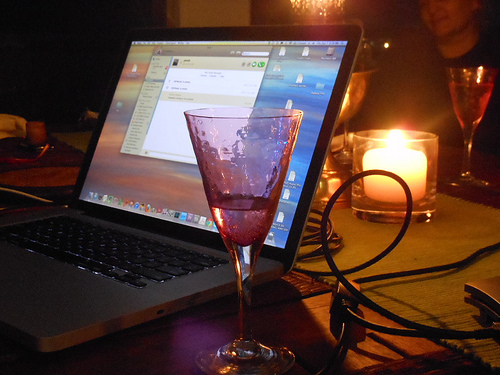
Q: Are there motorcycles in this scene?
A: No, there are no motorcycles.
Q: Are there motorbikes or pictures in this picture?
A: No, there are no motorbikes or pictures.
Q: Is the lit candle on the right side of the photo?
A: Yes, the candle is on the right of the image.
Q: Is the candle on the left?
A: No, the candle is on the right of the image.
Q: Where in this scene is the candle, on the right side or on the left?
A: The candle is on the right of the image.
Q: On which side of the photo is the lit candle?
A: The candle is on the right of the image.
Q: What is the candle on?
A: The candle is on the table.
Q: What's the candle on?
A: The candle is on the table.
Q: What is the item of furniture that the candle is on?
A: The piece of furniture is a table.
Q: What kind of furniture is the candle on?
A: The candle is on the table.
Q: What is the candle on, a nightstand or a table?
A: The candle is on a table.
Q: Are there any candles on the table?
A: Yes, there is a candle on the table.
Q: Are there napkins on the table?
A: No, there is a candle on the table.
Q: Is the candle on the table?
A: Yes, the candle is on the table.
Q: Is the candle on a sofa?
A: No, the candle is on the table.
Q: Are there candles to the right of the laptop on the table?
A: Yes, there is a candle to the right of the laptop.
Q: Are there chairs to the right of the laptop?
A: No, there is a candle to the right of the laptop.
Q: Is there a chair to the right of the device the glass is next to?
A: No, there is a candle to the right of the laptop.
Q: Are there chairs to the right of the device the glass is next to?
A: No, there is a candle to the right of the laptop.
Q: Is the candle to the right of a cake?
A: No, the candle is to the right of a laptop.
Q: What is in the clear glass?
A: The candle is in the glass.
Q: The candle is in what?
A: The candle is in the glass.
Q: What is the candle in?
A: The candle is in the glass.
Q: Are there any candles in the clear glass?
A: Yes, there is a candle in the glass.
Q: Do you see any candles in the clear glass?
A: Yes, there is a candle in the glass.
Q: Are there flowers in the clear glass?
A: No, there is a candle in the glass.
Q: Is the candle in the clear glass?
A: Yes, the candle is in the glass.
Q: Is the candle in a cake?
A: No, the candle is in the glass.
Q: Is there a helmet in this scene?
A: No, there are no helmets.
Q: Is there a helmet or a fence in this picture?
A: No, there are no helmets or fences.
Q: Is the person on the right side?
A: Yes, the person is on the right of the image.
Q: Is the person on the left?
A: No, the person is on the right of the image.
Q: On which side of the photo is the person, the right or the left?
A: The person is on the right of the image.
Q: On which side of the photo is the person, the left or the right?
A: The person is on the right of the image.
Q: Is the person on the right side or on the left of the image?
A: The person is on the right of the image.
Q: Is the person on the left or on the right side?
A: The person is on the right of the image.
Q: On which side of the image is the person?
A: The person is on the right of the image.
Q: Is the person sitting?
A: Yes, the person is sitting.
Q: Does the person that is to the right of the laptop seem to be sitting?
A: Yes, the person is sitting.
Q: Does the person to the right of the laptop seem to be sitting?
A: Yes, the person is sitting.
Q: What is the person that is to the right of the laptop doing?
A: The person is sitting.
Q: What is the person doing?
A: The person is sitting.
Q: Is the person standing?
A: No, the person is sitting.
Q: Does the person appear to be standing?
A: No, the person is sitting.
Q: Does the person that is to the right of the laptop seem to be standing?
A: No, the person is sitting.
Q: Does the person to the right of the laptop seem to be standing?
A: No, the person is sitting.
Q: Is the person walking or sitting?
A: The person is sitting.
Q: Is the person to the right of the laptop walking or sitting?
A: The person is sitting.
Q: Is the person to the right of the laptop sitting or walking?
A: The person is sitting.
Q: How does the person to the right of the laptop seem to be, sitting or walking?
A: The person is sitting.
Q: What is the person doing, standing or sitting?
A: The person is sitting.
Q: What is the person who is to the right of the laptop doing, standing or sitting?
A: The person is sitting.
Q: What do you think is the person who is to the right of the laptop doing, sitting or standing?
A: The person is sitting.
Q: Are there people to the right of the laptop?
A: Yes, there is a person to the right of the laptop.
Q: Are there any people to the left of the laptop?
A: No, the person is to the right of the laptop.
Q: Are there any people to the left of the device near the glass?
A: No, the person is to the right of the laptop.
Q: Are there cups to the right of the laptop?
A: No, there is a person to the right of the laptop.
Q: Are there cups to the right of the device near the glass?
A: No, there is a person to the right of the laptop.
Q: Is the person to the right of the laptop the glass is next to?
A: Yes, the person is to the right of the laptop.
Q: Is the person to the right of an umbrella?
A: No, the person is to the right of the laptop.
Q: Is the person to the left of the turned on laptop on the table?
A: No, the person is to the right of the laptop.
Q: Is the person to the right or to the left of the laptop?
A: The person is to the right of the laptop.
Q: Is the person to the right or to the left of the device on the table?
A: The person is to the right of the laptop.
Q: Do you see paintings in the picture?
A: No, there are no paintings.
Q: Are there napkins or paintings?
A: No, there are no paintings or napkins.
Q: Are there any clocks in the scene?
A: No, there are no clocks.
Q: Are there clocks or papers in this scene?
A: No, there are no clocks or papers.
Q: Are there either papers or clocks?
A: No, there are no clocks or papers.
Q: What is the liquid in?
A: The liquid is in the glass.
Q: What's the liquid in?
A: The liquid is in the glass.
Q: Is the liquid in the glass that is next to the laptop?
A: Yes, the liquid is in the glass.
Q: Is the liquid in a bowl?
A: No, the liquid is in the glass.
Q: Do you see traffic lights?
A: No, there are no traffic lights.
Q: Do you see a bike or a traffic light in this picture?
A: No, there are no traffic lights or bikes.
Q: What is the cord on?
A: The cord is on the table.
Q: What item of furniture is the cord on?
A: The cord is on the table.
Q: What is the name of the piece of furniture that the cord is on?
A: The piece of furniture is a table.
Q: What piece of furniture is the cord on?
A: The cord is on the table.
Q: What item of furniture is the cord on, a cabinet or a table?
A: The cord is on a table.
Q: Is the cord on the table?
A: Yes, the cord is on the table.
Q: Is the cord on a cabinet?
A: No, the cord is on the table.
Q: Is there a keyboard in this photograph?
A: Yes, there is a keyboard.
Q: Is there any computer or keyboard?
A: Yes, there is a keyboard.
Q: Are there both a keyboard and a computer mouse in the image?
A: No, there is a keyboard but no computer mice.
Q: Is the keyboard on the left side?
A: Yes, the keyboard is on the left of the image.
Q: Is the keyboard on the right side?
A: No, the keyboard is on the left of the image.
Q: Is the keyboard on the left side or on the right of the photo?
A: The keyboard is on the left of the image.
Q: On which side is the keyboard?
A: The keyboard is on the left of the image.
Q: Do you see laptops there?
A: Yes, there is a laptop.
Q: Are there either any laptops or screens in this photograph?
A: Yes, there is a laptop.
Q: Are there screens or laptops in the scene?
A: Yes, there is a laptop.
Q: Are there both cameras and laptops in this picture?
A: No, there is a laptop but no cameras.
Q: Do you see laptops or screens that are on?
A: Yes, the laptop is on.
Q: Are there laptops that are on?
A: Yes, there is a laptop that is on.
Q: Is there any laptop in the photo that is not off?
A: Yes, there is a laptop that is on.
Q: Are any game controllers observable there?
A: No, there are no game controllers.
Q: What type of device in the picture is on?
A: The device is a laptop.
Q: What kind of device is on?
A: The device is a laptop.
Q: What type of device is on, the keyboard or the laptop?
A: The laptop is on.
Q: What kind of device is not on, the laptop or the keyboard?
A: The keyboard is not on.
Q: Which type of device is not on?
A: The device is a keyboard.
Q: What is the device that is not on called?
A: The device is a keyboard.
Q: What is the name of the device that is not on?
A: The device is a keyboard.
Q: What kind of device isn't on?
A: The device is a keyboard.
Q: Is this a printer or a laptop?
A: This is a laptop.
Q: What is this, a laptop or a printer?
A: This is a laptop.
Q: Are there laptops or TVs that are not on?
A: No, there is a laptop but it is on.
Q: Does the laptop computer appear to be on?
A: Yes, the laptop computer is on.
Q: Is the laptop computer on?
A: Yes, the laptop computer is on.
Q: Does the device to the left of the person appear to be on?
A: Yes, the laptop computer is on.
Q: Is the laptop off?
A: No, the laptop is on.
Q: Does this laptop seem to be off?
A: No, the laptop is on.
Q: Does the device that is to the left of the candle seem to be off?
A: No, the laptop is on.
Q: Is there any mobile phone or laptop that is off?
A: No, there is a laptop but it is on.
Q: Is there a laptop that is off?
A: No, there is a laptop but it is on.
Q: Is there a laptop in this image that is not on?
A: No, there is a laptop but it is on.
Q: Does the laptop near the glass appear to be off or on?
A: The laptop computer is on.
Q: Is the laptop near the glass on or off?
A: The laptop computer is on.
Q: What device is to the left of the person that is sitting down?
A: The device is a laptop.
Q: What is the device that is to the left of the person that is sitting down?
A: The device is a laptop.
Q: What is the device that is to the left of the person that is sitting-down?
A: The device is a laptop.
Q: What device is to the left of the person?
A: The device is a laptop.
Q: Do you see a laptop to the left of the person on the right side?
A: Yes, there is a laptop to the left of the person.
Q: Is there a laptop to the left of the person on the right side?
A: Yes, there is a laptop to the left of the person.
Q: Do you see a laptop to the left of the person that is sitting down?
A: Yes, there is a laptop to the left of the person.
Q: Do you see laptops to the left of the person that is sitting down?
A: Yes, there is a laptop to the left of the person.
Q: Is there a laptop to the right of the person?
A: No, the laptop is to the left of the person.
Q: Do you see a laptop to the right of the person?
A: No, the laptop is to the left of the person.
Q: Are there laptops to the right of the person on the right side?
A: No, the laptop is to the left of the person.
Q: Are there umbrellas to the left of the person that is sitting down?
A: No, there is a laptop to the left of the person.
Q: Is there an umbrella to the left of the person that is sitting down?
A: No, there is a laptop to the left of the person.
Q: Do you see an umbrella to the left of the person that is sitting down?
A: No, there is a laptop to the left of the person.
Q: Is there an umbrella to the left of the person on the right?
A: No, there is a laptop to the left of the person.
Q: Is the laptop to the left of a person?
A: Yes, the laptop is to the left of a person.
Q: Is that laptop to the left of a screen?
A: No, the laptop is to the left of a person.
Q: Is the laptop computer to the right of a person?
A: No, the laptop computer is to the left of a person.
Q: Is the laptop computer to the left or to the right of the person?
A: The laptop computer is to the left of the person.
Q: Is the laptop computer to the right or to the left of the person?
A: The laptop computer is to the left of the person.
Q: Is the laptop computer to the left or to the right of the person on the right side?
A: The laptop computer is to the left of the person.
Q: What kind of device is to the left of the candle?
A: The device is a laptop.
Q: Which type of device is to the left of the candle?
A: The device is a laptop.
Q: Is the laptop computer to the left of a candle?
A: Yes, the laptop computer is to the left of a candle.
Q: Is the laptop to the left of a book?
A: No, the laptop is to the left of a candle.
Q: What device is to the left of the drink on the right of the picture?
A: The device is a laptop.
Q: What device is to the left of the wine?
A: The device is a laptop.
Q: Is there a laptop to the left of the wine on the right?
A: Yes, there is a laptop to the left of the wine.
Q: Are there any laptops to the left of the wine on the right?
A: Yes, there is a laptop to the left of the wine.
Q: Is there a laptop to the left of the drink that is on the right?
A: Yes, there is a laptop to the left of the wine.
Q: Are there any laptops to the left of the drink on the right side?
A: Yes, there is a laptop to the left of the wine.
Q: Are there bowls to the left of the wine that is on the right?
A: No, there is a laptop to the left of the wine.